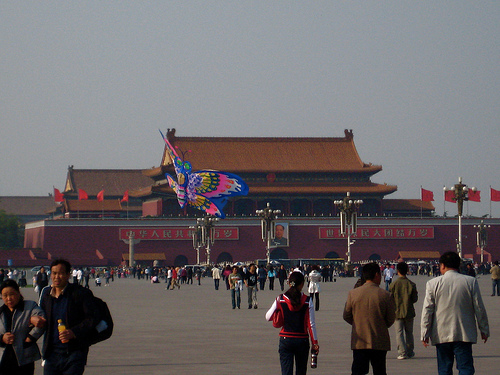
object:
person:
[228, 265, 243, 309]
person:
[343, 262, 392, 375]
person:
[265, 272, 318, 374]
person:
[386, 261, 418, 361]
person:
[170, 266, 181, 290]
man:
[30, 259, 114, 373]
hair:
[285, 271, 306, 309]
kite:
[155, 128, 248, 218]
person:
[419, 250, 491, 375]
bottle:
[57, 319, 68, 343]